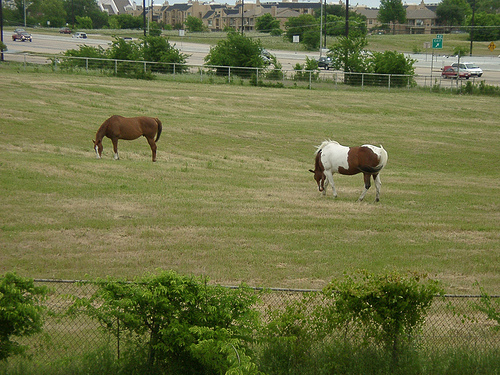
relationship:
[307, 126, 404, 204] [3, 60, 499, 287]
horse standing in pasture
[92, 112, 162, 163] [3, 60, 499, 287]
horse standing in pasture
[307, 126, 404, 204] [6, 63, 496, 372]
horse standing in pasture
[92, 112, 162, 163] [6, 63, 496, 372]
horse standing in pasture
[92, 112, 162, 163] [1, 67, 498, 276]
horse eating grass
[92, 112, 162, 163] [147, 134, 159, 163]
horse has leg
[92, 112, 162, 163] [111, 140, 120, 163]
horse has leg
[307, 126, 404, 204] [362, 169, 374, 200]
horse has leg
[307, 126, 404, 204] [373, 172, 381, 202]
horse has leg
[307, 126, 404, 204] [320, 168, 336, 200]
horse has leg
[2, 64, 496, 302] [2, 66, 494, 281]
grass growing in field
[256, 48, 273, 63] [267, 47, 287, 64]
car on road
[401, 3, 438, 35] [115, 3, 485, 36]
building by trees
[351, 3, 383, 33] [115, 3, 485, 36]
building by trees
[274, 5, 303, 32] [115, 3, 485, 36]
building by trees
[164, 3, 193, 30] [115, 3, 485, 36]
building by trees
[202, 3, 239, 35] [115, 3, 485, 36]
building by trees